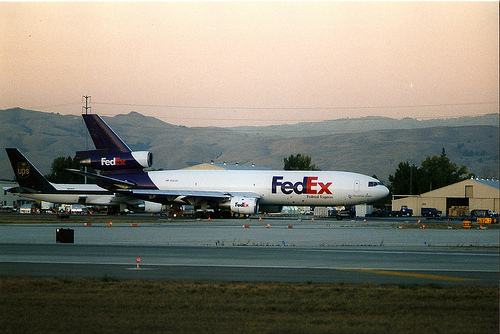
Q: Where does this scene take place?
A: At an airport.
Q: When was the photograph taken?
A: At sunset.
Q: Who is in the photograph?
A: No one.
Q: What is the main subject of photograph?
A: Airplane.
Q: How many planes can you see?
A: 2.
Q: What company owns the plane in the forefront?
A: FedEx.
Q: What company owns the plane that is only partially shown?
A: UPS.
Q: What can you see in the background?
A: Large hills.